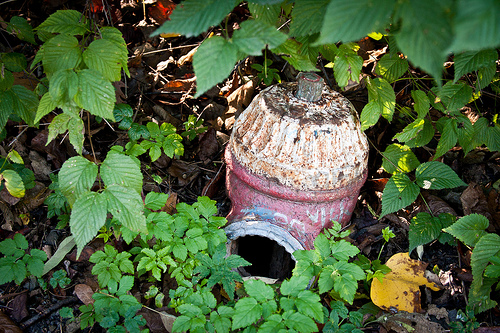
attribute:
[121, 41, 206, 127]
leaflets — dry, brown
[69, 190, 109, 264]
leafs — green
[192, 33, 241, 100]
leaf — green, dry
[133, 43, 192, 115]
brown — green, dead, dry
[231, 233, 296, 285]
hole — round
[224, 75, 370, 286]
hydrant — dry, red, white, old, abandoned, fading, metal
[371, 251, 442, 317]
leaf — yellow, decaying, dry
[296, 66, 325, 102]
bolt — rusty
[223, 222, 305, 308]
hole — open, round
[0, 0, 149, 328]
plant — small, green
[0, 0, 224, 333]
plants — healthy, green, growing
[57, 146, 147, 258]
four leaves — small, green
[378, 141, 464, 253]
leaves — green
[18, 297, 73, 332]
twig — small